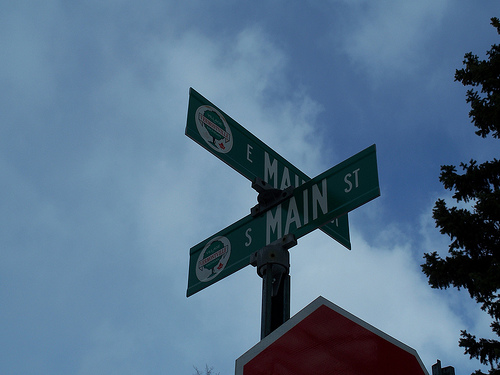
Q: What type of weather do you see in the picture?
A: It is overcast.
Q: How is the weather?
A: It is overcast.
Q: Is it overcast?
A: Yes, it is overcast.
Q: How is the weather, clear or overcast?
A: It is overcast.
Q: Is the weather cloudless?
A: No, it is overcast.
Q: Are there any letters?
A: Yes, there are letters.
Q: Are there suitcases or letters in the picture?
A: Yes, there are letters.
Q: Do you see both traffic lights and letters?
A: No, there are letters but no traffic lights.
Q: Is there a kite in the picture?
A: No, there are no kites.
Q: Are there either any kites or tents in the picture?
A: No, there are no kites or tents.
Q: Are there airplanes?
A: No, there are no airplanes.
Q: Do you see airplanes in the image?
A: No, there are no airplanes.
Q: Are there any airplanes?
A: No, there are no airplanes.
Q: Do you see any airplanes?
A: No, there are no airplanes.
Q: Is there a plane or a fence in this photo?
A: No, there are no airplanes or fences.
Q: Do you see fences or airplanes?
A: No, there are no airplanes or fences.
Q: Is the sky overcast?
A: Yes, the sky is overcast.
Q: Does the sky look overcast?
A: Yes, the sky is overcast.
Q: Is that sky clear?
A: No, the sky is overcast.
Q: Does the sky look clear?
A: No, the sky is overcast.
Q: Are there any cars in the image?
A: No, there are no cars.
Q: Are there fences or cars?
A: No, there are no cars or fences.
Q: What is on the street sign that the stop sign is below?
A: The tree is on the street sign.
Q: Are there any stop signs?
A: Yes, there is a stop sign.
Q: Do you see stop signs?
A: Yes, there is a stop sign.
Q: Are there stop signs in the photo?
A: Yes, there is a stop sign.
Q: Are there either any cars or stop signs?
A: Yes, there is a stop sign.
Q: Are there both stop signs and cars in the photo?
A: No, there is a stop sign but no cars.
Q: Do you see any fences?
A: No, there are no fences.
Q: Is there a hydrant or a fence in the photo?
A: No, there are no fences or fire hydrants.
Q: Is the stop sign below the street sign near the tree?
A: Yes, the stop sign is below the street sign.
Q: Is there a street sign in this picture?
A: Yes, there is a street sign.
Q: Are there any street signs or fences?
A: Yes, there is a street sign.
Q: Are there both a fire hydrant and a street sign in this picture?
A: No, there is a street sign but no fire hydrants.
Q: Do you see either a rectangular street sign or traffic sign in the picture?
A: Yes, there is a rectangular street sign.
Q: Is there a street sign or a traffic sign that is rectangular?
A: Yes, the street sign is rectangular.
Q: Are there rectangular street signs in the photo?
A: Yes, there is a rectangular street sign.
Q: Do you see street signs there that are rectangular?
A: Yes, there is a street sign that is rectangular.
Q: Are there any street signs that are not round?
A: Yes, there is a rectangular street sign.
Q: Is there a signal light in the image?
A: No, there are no traffic lights.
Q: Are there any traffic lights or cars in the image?
A: No, there are no traffic lights or cars.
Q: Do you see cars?
A: No, there are no cars.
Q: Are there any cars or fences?
A: No, there are no cars or fences.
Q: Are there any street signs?
A: Yes, there is a street sign.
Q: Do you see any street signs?
A: Yes, there is a street sign.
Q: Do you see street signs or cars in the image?
A: Yes, there is a street sign.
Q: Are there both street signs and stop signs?
A: Yes, there are both a street sign and a stop sign.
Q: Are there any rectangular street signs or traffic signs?
A: Yes, there is a rectangular street sign.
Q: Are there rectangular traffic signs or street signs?
A: Yes, there is a rectangular street sign.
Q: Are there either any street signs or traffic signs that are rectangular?
A: Yes, the street sign is rectangular.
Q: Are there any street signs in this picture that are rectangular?
A: Yes, there is a rectangular street sign.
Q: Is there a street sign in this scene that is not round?
A: Yes, there is a rectangular street sign.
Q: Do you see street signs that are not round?
A: Yes, there is a rectangular street sign.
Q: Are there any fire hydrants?
A: No, there are no fire hydrants.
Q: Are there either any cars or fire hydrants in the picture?
A: No, there are no fire hydrants or cars.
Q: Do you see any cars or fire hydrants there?
A: No, there are no fire hydrants or cars.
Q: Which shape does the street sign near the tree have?
A: The street sign has rectangular shape.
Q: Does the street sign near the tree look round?
A: No, the street sign is rectangular.